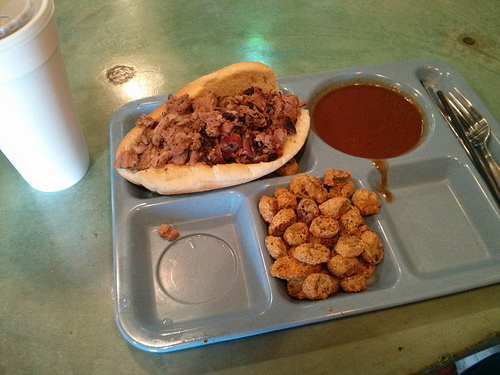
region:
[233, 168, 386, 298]
breadcrumbs on blue tray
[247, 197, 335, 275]
breadcrumbs on blue tray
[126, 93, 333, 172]
sandwich with red meat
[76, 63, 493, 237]
tray is grey and rectangle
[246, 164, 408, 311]
breadcrumbs are brown and crumbled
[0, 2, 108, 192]
a styrofoam cup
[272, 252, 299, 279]
a chunk of food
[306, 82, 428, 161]
some sauce or some soup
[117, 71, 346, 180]
a sandwich that appears to have meat in it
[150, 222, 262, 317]
an empty part of the tray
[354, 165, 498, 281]
another empty part of the tray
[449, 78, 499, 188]
a fork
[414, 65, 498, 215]
a knife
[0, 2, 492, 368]
the table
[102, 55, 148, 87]
a dent in the table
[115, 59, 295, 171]
beef taco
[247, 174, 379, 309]
potatoes on tray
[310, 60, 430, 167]
brown barbecue sauce on tray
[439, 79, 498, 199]
gray metal fork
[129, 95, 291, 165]
meat in sandwich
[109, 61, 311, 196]
white sandwich bread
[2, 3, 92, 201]
white styrofoam cup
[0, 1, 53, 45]
clear plastic lid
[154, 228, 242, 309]
circle on plastic tray